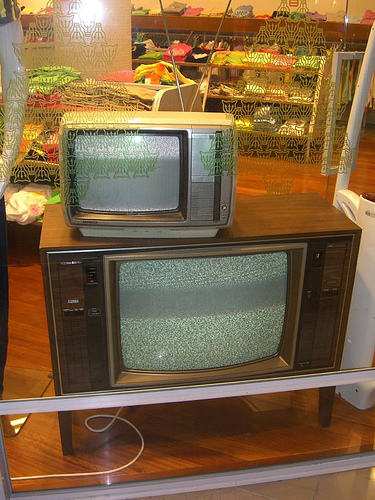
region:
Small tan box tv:
[59, 100, 236, 240]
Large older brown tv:
[18, 196, 364, 460]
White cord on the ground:
[5, 399, 146, 491]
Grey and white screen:
[112, 245, 296, 376]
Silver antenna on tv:
[144, 1, 237, 134]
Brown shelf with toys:
[188, 43, 326, 173]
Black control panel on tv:
[79, 263, 97, 286]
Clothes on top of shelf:
[12, 74, 186, 119]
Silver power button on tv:
[219, 199, 231, 215]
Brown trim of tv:
[101, 237, 313, 395]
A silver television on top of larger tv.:
[57, 110, 237, 237]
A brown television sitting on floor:
[38, 191, 363, 456]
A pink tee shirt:
[164, 42, 192, 58]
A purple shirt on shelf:
[303, 10, 326, 20]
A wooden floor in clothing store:
[0, 124, 373, 499]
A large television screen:
[114, 250, 291, 371]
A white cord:
[10, 405, 145, 481]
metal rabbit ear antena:
[160, 0, 232, 111]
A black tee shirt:
[183, 46, 212, 64]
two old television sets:
[19, 87, 369, 446]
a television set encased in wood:
[22, 181, 372, 446]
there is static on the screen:
[109, 253, 304, 378]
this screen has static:
[66, 125, 189, 220]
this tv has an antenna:
[32, 5, 277, 234]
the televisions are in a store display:
[20, 80, 372, 477]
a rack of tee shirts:
[145, 29, 347, 177]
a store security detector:
[327, 0, 373, 378]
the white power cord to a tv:
[6, 393, 169, 487]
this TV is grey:
[46, 100, 255, 249]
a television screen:
[118, 265, 293, 361]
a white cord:
[117, 454, 131, 469]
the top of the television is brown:
[259, 202, 322, 229]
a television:
[56, 115, 231, 231]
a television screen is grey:
[75, 136, 174, 211]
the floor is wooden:
[181, 414, 276, 454]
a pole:
[348, 90, 363, 132]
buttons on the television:
[85, 267, 96, 284]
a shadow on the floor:
[228, 405, 283, 426]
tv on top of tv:
[59, 112, 236, 236]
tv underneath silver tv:
[40, 192, 360, 457]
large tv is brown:
[38, 193, 364, 456]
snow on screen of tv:
[118, 252, 288, 372]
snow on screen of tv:
[74, 132, 180, 212]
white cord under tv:
[9, 404, 144, 480]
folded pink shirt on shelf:
[164, 38, 191, 55]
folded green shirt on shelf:
[139, 48, 165, 58]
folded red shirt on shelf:
[40, 124, 59, 154]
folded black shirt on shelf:
[184, 43, 210, 62]